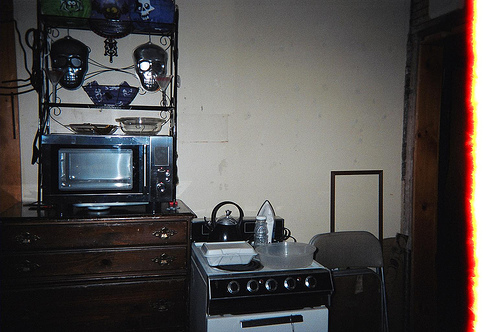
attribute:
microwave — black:
[40, 131, 177, 213]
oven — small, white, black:
[188, 213, 335, 331]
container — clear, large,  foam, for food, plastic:
[253, 238, 320, 270]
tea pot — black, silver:
[201, 201, 245, 240]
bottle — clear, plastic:
[253, 215, 269, 245]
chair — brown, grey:
[308, 230, 395, 331]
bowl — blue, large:
[80, 80, 140, 108]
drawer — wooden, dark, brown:
[2, 196, 200, 329]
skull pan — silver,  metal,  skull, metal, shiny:
[131, 39, 171, 92]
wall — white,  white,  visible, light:
[13, 1, 408, 244]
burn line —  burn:
[463, 3, 500, 330]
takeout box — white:
[198, 239, 260, 267]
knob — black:
[157, 182, 168, 195]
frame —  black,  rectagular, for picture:
[330, 167, 383, 246]